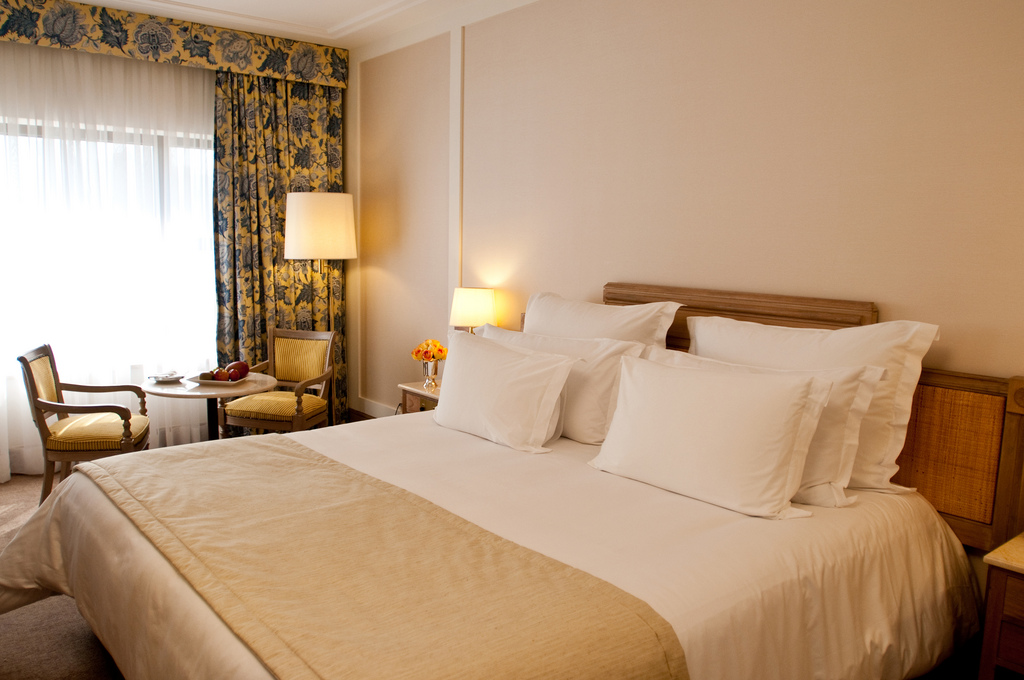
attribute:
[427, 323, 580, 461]
pillow — white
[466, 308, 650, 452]
pillow — white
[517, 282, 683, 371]
pillow — white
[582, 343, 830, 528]
pillow — white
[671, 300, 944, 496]
pillow — white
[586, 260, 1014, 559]
head board — brown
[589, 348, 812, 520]
pillow — smallest  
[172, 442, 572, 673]
coverlet — beige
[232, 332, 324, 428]
chairs — wooden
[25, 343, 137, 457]
chairs — wooden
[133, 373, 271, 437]
table — round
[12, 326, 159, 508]
chair — one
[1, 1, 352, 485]
window — large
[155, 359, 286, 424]
table — round, small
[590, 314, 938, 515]
three pillows — Three 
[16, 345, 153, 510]
chair — wooden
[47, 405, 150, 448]
cushion — yellow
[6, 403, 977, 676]
sheets — white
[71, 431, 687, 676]
blanket — brown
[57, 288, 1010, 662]
bed — white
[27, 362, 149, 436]
upholstery — beige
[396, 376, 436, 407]
table — bedside 